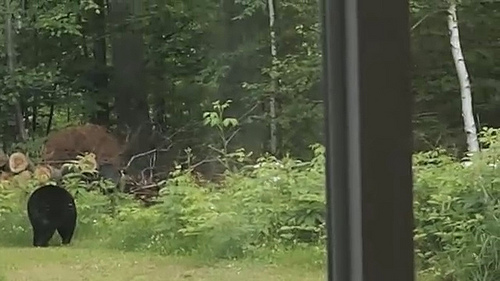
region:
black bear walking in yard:
[27, 183, 76, 249]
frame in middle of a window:
[326, 0, 415, 280]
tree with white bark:
[446, 0, 481, 153]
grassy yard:
[2, 243, 327, 280]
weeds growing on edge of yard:
[0, 127, 499, 279]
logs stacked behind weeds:
[0, 150, 55, 187]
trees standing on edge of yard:
[0, 0, 322, 175]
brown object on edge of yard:
[46, 121, 122, 168]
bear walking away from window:
[26, 185, 76, 247]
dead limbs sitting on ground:
[122, 124, 242, 197]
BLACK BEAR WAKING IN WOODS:
[23, 180, 82, 246]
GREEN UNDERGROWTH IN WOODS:
[125, 216, 180, 241]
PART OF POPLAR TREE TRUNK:
[260, 8, 280, 58]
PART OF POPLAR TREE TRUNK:
[440, 2, 470, 57]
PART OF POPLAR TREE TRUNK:
[462, 85, 477, 137]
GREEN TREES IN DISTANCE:
[24, 13, 71, 42]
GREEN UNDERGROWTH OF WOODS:
[431, 178, 476, 246]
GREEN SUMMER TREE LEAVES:
[290, 50, 323, 119]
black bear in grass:
[16, 166, 101, 261]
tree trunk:
[440, 12, 487, 172]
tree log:
[4, 146, 34, 178]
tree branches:
[111, 127, 208, 199]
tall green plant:
[193, 99, 258, 195]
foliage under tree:
[417, 133, 493, 279]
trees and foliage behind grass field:
[4, 3, 494, 245]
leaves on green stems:
[476, 120, 494, 145]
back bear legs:
[25, 225, 82, 248]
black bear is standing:
[21, 169, 93, 246]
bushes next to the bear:
[142, 165, 284, 240]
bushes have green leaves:
[152, 149, 294, 260]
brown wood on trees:
[65, 18, 229, 216]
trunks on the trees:
[88, 58, 228, 199]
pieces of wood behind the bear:
[7, 136, 45, 186]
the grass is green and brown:
[105, 218, 213, 278]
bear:
[13, 171, 89, 247]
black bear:
[21, 177, 83, 248]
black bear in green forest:
[18, 175, 85, 249]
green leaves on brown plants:
[177, 187, 199, 204]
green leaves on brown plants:
[237, 194, 270, 223]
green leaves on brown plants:
[286, 184, 323, 202]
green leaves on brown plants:
[451, 224, 479, 256]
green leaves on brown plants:
[90, 195, 108, 219]